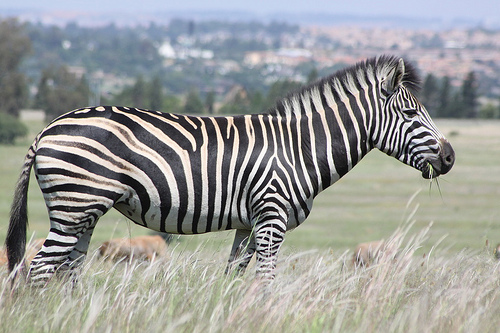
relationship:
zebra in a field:
[0, 54, 454, 288] [348, 183, 395, 225]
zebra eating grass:
[14, 58, 454, 290] [338, 177, 460, 241]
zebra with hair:
[0, 54, 454, 288] [273, 53, 420, 115]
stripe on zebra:
[20, 82, 441, 289] [0, 54, 454, 288]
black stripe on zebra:
[331, 106, 346, 176] [0, 54, 454, 288]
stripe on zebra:
[297, 89, 319, 194] [0, 54, 454, 288]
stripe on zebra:
[20, 82, 441, 289] [2, 43, 462, 310]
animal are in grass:
[1, 55, 458, 300] [0, 105, 496, 332]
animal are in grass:
[354, 235, 394, 264] [0, 105, 496, 332]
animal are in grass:
[93, 232, 177, 262] [0, 105, 496, 332]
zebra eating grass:
[14, 58, 454, 290] [418, 150, 471, 187]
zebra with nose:
[0, 54, 454, 288] [409, 123, 470, 219]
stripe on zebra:
[20, 82, 441, 289] [36, 67, 483, 259]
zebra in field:
[0, 54, 454, 288] [16, 120, 481, 330]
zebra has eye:
[0, 54, 454, 288] [406, 107, 416, 116]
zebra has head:
[0, 54, 454, 288] [326, 13, 472, 235]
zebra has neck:
[0, 54, 454, 288] [293, 72, 373, 202]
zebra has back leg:
[0, 54, 454, 288] [25, 197, 115, 293]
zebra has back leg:
[0, 54, 454, 288] [57, 220, 98, 288]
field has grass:
[5, 122, 469, 320] [0, 105, 496, 332]